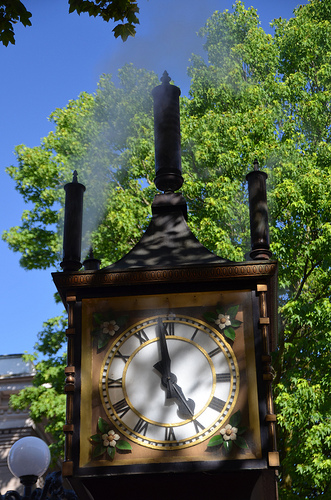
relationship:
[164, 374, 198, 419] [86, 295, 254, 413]
minute hand on clock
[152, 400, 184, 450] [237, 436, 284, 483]
middle of clock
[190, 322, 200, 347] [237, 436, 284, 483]
one on clock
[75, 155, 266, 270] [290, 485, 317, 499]
placed outside yard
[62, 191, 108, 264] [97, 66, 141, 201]
venting gray smoke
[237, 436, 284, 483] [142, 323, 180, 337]
clock tells time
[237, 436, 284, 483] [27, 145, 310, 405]
clock not wooden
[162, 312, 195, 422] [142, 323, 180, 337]
hands tell time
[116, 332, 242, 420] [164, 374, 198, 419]
numbers tell hour